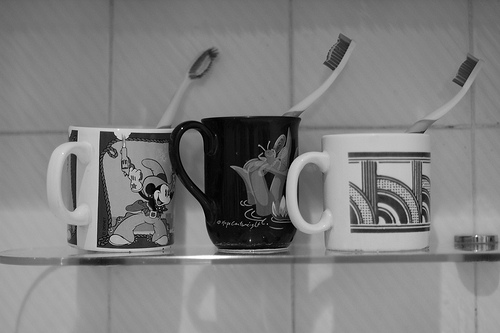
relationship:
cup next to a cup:
[170, 111, 301, 253] [48, 124, 177, 258]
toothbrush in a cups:
[408, 51, 482, 135] [286, 131, 431, 257]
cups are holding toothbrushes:
[42, 111, 438, 258] [137, 33, 485, 131]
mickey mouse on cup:
[109, 154, 173, 247] [48, 124, 177, 258]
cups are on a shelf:
[42, 111, 438, 258] [1, 245, 500, 264]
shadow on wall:
[181, 259, 308, 333] [2, 0, 500, 332]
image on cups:
[350, 154, 431, 230] [286, 131, 431, 257]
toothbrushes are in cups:
[137, 33, 485, 131] [42, 111, 438, 258]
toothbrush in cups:
[408, 51, 482, 135] [286, 131, 431, 257]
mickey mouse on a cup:
[109, 154, 173, 247] [48, 124, 177, 258]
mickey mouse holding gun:
[109, 154, 173, 247] [119, 129, 132, 177]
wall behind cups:
[2, 0, 500, 332] [42, 111, 438, 258]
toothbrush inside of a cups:
[408, 51, 482, 135] [286, 131, 431, 257]